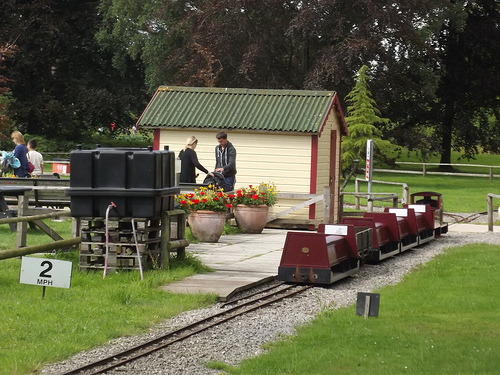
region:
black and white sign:
[18, 253, 92, 308]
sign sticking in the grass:
[16, 249, 83, 309]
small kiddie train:
[271, 183, 456, 293]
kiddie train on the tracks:
[264, 181, 459, 298]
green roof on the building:
[130, 77, 327, 134]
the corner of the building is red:
[308, 132, 320, 219]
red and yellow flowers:
[173, 180, 231, 212]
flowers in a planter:
[221, 180, 274, 235]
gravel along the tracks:
[36, 215, 461, 373]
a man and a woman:
[176, 124, 241, 194]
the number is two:
[21, 246, 78, 288]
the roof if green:
[125, 70, 347, 162]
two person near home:
[143, 117, 286, 209]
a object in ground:
[339, 278, 400, 345]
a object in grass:
[344, 279, 405, 336]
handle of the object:
[356, 294, 380, 324]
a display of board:
[4, 238, 104, 298]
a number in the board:
[8, 242, 105, 305]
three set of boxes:
[67, 145, 188, 227]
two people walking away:
[6, 131, 56, 212]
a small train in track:
[257, 184, 486, 298]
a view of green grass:
[281, 258, 499, 365]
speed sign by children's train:
[9, 253, 80, 293]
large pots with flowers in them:
[187, 180, 272, 245]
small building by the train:
[162, 67, 351, 236]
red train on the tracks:
[287, 178, 452, 277]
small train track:
[147, 306, 214, 353]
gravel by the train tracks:
[196, 336, 256, 358]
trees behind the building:
[121, 10, 433, 89]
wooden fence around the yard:
[399, 158, 499, 192]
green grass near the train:
[433, 276, 476, 368]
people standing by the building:
[176, 120, 243, 197]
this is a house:
[112, 45, 379, 244]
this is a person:
[194, 115, 242, 202]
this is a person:
[153, 100, 217, 211]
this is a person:
[1, 130, 34, 197]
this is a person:
[19, 130, 58, 216]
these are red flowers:
[170, 183, 202, 220]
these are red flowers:
[221, 180, 242, 208]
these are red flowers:
[241, 180, 266, 216]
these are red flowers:
[209, 182, 236, 225]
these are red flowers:
[202, 182, 230, 212]